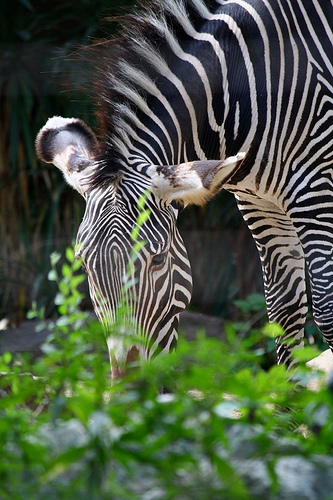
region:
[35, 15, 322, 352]
black and white striped zebra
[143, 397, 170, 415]
green leaves on brown branches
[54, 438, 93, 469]
green leaves on brown branches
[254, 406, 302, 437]
green leaves on brown branches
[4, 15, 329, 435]
the picture of the zebra is up close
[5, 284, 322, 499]
The plants are blurry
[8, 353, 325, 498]
The plants are green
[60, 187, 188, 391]
The head of the zebra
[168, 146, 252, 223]
The right ear of the zebra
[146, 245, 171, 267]
the right eye of the zebra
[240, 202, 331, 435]
The front legs of the zebra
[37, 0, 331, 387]
this is a zebra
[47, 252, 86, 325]
these are leaves on a branch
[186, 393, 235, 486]
these are leaves on a branch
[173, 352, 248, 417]
these are leaves on a branch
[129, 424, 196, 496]
these are leaves on a branch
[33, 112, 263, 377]
the head of a zebra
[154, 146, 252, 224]
the ear of a zebra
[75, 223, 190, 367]
A zebra's head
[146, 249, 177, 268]
Eye of a zebra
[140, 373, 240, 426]
Green leaves of a tree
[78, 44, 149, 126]
Fur on the zebra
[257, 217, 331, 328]
Legs of a zebra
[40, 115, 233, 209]
Ears of a zebra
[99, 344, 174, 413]
Muzzle of a zebra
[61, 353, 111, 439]
Green plants growing in the field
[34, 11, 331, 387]
a zebra with tilted ears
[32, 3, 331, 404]
zebra hiding behind leaves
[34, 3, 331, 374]
a striped mammal with a mane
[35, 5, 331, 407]
a zebra feeding on a yard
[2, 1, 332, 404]
a zebra eating plants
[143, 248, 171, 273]
the eye is black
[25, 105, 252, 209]
the ears are long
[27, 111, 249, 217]
ears are white and black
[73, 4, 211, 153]
mane of zebra on the neck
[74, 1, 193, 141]
border of mane is black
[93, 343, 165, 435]
muzzle of zebra is black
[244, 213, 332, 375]
the front legs of zebra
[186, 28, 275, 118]
thick stripes of zebra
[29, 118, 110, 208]
ear of the zebra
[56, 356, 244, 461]
leaves on the plant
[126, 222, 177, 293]
eye of the zebra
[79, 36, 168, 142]
hair on back of zebra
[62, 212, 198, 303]
two eyes on the zebra